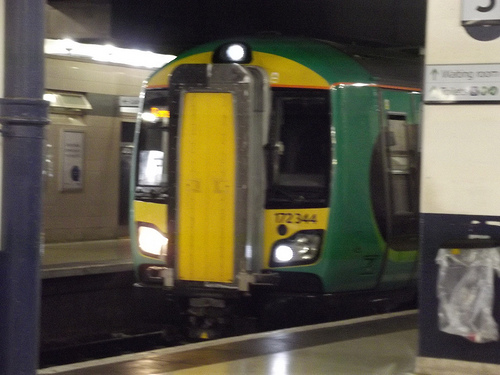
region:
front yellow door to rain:
[192, 50, 266, 279]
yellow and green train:
[127, 26, 355, 337]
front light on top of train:
[218, 23, 262, 72]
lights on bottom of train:
[20, 217, 323, 312]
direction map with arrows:
[416, 60, 498, 139]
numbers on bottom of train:
[268, 188, 323, 249]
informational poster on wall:
[6, 122, 98, 207]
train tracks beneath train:
[39, 278, 167, 368]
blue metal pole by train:
[0, 26, 73, 359]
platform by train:
[178, 302, 438, 369]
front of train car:
[116, 39, 338, 312]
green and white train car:
[118, 30, 418, 310]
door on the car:
[159, 82, 245, 298]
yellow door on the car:
[166, 81, 248, 304]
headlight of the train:
[266, 229, 320, 264]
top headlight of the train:
[206, 35, 261, 81]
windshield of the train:
[269, 92, 326, 196]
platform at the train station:
[38, 233, 128, 280]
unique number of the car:
[258, 203, 325, 241]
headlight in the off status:
[296, 232, 319, 263]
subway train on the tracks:
[135, 55, 410, 297]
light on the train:
[264, 225, 314, 282]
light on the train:
[124, 204, 184, 278]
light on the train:
[212, 23, 261, 85]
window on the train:
[265, 83, 340, 213]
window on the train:
[136, 90, 186, 214]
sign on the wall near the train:
[55, 125, 89, 205]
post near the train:
[2, 72, 66, 367]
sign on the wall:
[427, 50, 494, 145]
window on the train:
[377, 103, 414, 220]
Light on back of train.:
[256, 213, 303, 282]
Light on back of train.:
[126, 209, 207, 269]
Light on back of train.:
[216, 32, 250, 74]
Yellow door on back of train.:
[161, 94, 220, 324]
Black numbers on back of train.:
[250, 205, 356, 250]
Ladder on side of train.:
[361, 122, 408, 289]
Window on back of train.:
[268, 63, 303, 203]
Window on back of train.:
[124, 110, 182, 226]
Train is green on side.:
[337, 77, 389, 263]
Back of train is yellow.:
[129, 49, 331, 295]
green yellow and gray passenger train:
[162, 41, 370, 286]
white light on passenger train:
[265, 232, 307, 264]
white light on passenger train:
[138, 220, 172, 262]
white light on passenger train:
[143, 148, 160, 178]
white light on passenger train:
[218, 42, 244, 65]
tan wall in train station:
[430, 116, 481, 196]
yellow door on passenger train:
[185, 96, 232, 266]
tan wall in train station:
[52, 208, 102, 232]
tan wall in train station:
[93, 139, 111, 186]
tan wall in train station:
[58, 65, 128, 90]